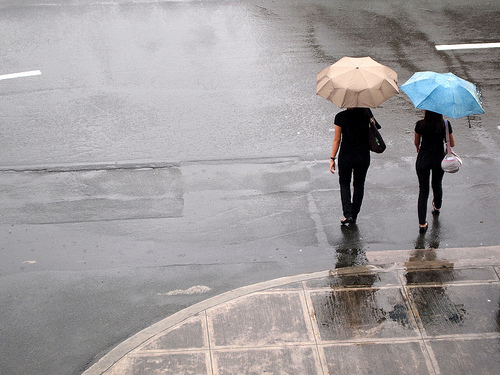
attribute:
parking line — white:
[432, 30, 472, 65]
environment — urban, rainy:
[59, 133, 204, 223]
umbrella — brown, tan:
[311, 52, 401, 112]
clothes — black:
[334, 109, 381, 217]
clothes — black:
[411, 118, 452, 223]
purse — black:
[365, 110, 387, 155]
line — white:
[431, 37, 496, 59]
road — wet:
[4, 6, 496, 372]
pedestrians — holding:
[323, 109, 475, 252]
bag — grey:
[442, 146, 464, 176]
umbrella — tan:
[318, 50, 398, 107]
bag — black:
[363, 124, 386, 151]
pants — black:
[412, 150, 446, 220]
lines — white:
[2, 56, 42, 86]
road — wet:
[0, 4, 500, 165]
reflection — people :
[302, 233, 482, 349]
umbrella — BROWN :
[307, 45, 414, 115]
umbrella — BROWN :
[301, 42, 405, 107]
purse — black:
[366, 104, 388, 154]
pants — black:
[411, 153, 445, 231]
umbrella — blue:
[396, 67, 488, 122]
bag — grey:
[439, 114, 467, 176]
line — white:
[2, 62, 43, 93]